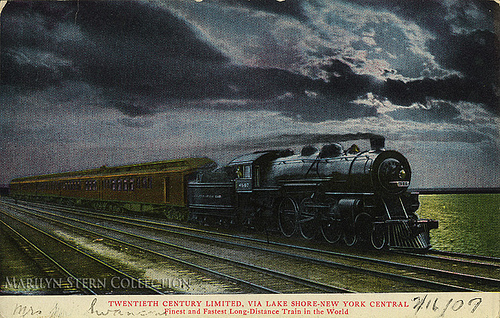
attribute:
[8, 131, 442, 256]
train — old, side, black, part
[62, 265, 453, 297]
line — twentieth century limited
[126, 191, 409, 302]
rail — dge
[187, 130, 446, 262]
engine — black train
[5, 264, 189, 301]
name — marilyn stern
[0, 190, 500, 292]
rail — edge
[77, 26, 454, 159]
sky — dark, cloudy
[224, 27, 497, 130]
cloud — part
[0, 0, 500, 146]
clouds — distant 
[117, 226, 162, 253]
rail — part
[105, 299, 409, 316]
words — red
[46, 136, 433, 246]
train cars — yellow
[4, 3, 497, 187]
clouds — above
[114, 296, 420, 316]
card — bottom 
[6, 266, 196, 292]
wording — white 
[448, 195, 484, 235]
field — green